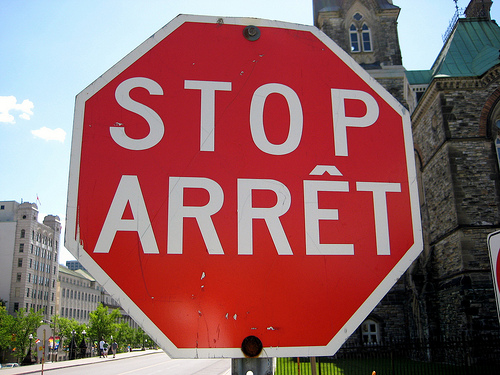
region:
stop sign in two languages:
[55, 10, 430, 374]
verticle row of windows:
[8, 211, 28, 296]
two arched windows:
[343, 15, 375, 57]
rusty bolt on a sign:
[235, 329, 266, 361]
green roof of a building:
[404, 12, 499, 83]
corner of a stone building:
[433, 81, 471, 340]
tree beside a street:
[55, 314, 87, 374]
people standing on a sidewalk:
[93, 335, 122, 362]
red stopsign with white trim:
[60, 7, 425, 373]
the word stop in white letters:
[91, 60, 388, 159]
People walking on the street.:
[97, 335, 122, 358]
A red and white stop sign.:
[63, 13, 424, 360]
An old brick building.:
[291, 0, 498, 373]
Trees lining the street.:
[0, 300, 160, 367]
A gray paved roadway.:
[17, 350, 232, 373]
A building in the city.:
[0, 201, 61, 332]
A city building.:
[59, 263, 101, 328]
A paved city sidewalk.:
[1, 346, 165, 373]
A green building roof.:
[403, 16, 498, 80]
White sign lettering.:
[94, 76, 402, 256]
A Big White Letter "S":
[105, 73, 165, 155]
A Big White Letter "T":
[175, 67, 235, 162]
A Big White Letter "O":
[245, 70, 300, 161]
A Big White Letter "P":
[310, 76, 387, 157]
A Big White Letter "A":
[92, 161, 159, 271]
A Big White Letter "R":
[155, 165, 225, 265]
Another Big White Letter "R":
[230, 155, 295, 270]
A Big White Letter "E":
[295, 155, 355, 280]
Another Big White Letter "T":
[350, 170, 400, 260]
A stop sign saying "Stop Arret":
[90, 66, 395, 261]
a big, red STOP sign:
[73, 28, 418, 368]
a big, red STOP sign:
[88, 47, 307, 312]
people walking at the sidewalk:
[88, 328, 121, 360]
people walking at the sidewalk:
[63, 322, 130, 361]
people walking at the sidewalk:
[76, 326, 148, 371]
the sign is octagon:
[87, 23, 417, 363]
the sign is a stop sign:
[126, 77, 394, 305]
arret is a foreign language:
[101, 172, 403, 271]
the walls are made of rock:
[437, 90, 487, 332]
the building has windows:
[61, 282, 106, 331]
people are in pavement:
[91, 338, 123, 360]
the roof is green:
[454, 32, 494, 68]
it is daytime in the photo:
[11, 21, 491, 364]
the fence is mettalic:
[372, 338, 474, 371]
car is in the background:
[2, 351, 34, 370]